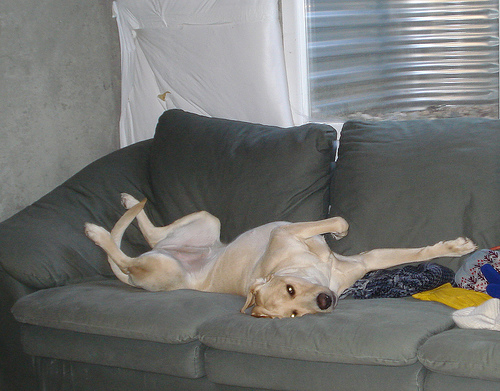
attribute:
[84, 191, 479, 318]
dog — laying, tan, stretched, white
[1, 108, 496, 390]
couch — gray, grey, comfy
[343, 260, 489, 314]
objects — black, yellow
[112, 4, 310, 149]
sheet — white, plastic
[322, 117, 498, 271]
pillow — grey, couch pillow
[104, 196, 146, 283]
tail — curled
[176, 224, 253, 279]
belly — pointing up, exposed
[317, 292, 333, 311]
nose — black, dark black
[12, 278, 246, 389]
cushion — blue, dark grey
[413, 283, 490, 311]
glove — yellow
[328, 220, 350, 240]
paw — bent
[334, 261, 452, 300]
blanket — blue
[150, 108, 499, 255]
pillows — gray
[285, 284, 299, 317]
eyes — dark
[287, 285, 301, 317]
eyeballs — glaring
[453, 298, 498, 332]
object — white